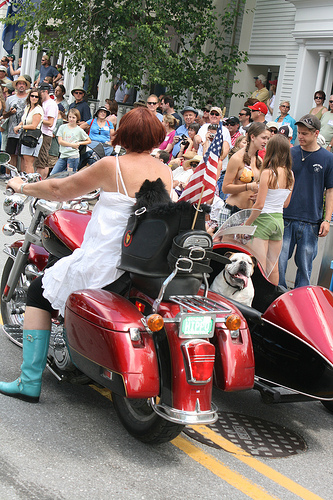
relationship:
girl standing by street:
[210, 122, 273, 220] [4, 333, 332, 497]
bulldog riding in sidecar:
[211, 251, 255, 311] [208, 243, 330, 415]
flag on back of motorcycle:
[171, 121, 224, 204] [1, 173, 255, 445]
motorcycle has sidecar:
[1, 173, 255, 445] [208, 243, 330, 415]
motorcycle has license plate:
[1, 173, 255, 445] [180, 313, 218, 340]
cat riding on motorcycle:
[129, 177, 176, 218] [1, 173, 255, 445]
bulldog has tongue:
[211, 251, 255, 311] [234, 271, 251, 287]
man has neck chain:
[280, 113, 332, 289] [298, 146, 321, 164]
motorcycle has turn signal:
[1, 173, 255, 445] [128, 325, 146, 346]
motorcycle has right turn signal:
[1, 173, 255, 445] [228, 328, 243, 341]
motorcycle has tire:
[1, 173, 255, 445] [113, 298, 185, 445]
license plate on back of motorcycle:
[180, 313, 218, 340] [1, 173, 255, 445]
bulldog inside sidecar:
[211, 251, 255, 311] [208, 243, 330, 415]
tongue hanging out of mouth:
[234, 271, 251, 287] [228, 266, 250, 289]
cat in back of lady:
[129, 177, 176, 218] [1, 104, 180, 403]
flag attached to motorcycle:
[171, 121, 224, 204] [1, 173, 255, 445]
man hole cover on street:
[180, 410, 311, 459] [4, 333, 332, 497]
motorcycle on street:
[1, 173, 255, 445] [4, 333, 332, 497]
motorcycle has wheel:
[1, 173, 255, 445] [3, 244, 54, 329]